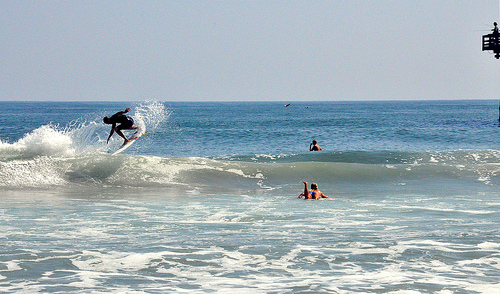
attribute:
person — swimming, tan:
[308, 138, 323, 155]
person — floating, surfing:
[296, 175, 325, 204]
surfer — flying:
[92, 109, 138, 138]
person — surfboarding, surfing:
[92, 106, 144, 142]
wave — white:
[81, 123, 168, 162]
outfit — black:
[111, 114, 136, 130]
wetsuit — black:
[111, 108, 134, 133]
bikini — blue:
[307, 188, 317, 197]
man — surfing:
[101, 114, 141, 144]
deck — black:
[485, 25, 499, 56]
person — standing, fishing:
[478, 16, 498, 33]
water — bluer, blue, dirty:
[5, 100, 499, 290]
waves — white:
[0, 129, 71, 188]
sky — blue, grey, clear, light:
[1, 1, 494, 97]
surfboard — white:
[109, 127, 146, 155]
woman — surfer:
[299, 174, 330, 203]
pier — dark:
[479, 29, 497, 54]